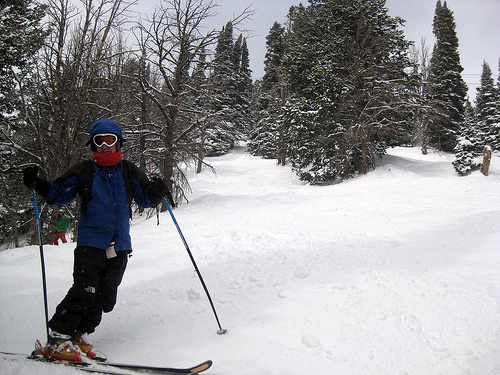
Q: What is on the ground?
A: Snow.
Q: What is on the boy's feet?
A: Skis.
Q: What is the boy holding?
A: Ski poles.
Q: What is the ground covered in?
A: Snow.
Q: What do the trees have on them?
A: Snow.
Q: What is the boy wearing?
A: Snow gear.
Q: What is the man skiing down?
A: A small hill.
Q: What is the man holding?
A: Ski poles.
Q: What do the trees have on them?
A: Snow.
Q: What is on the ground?
A: Snow.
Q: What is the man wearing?
A: Black pants.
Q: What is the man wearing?
A: A blue jacket.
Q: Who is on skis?
A: A man.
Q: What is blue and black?
A: A ski jacket.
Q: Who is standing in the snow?
A: A skier.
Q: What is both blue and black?
A: A ski jacket.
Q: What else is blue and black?
A: Ski poles.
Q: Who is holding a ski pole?
A: A snow skier.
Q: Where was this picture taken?
A: On a ski mountain.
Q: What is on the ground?
A: Snow.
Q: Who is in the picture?
A: A skier.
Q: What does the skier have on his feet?
A: Skis.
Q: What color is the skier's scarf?
A: Red.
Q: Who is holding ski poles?
A: The skier.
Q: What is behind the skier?
A: Trees.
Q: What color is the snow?
A: White.